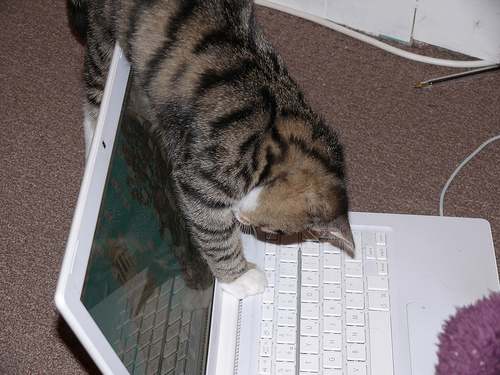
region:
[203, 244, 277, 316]
white paw of a cat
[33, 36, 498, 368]
white plastic laptop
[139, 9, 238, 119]
black stripes on a cat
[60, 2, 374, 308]
cat standing on laptop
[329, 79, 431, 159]
brown carpet on floor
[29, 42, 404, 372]
laptop on brown carpet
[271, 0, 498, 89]
white wire on carpet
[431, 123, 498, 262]
white cord attached to laptop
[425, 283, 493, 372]
purple fuzzy cloth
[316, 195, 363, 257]
ear of a cat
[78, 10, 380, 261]
This is a cat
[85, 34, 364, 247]
The cat is draped over a laptop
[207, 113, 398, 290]
The cat is looking at the computer screen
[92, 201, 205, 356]
There are many icons on the computer screen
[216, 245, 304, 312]
The cat's paw is on the keyboard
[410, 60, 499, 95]
Pen laying on the floor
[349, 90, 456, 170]
The floor is covered by carpet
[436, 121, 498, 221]
Cord connected to the computer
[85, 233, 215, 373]
Something that resembles the Capitol Building on the desktop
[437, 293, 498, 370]
Purple object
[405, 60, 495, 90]
a Bic pen on the carpet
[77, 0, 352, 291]
a tabby cat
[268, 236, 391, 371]
white keyboard of a laptop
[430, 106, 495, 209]
a gray wire on the carpet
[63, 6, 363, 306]
a cat touching a laptop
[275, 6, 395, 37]
a white wire along the wall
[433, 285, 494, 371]
fluffy purple fabric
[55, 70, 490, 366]
a white laptop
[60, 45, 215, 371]
opened lid of a laptop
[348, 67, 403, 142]
a brown carpet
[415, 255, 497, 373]
purple fuzzy toy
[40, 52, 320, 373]
a laptop computer screen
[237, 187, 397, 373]
white keyboard on a computer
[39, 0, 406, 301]
cat playing on laptop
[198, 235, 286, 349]
white cat paw on the computer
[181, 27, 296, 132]
gray and black stripes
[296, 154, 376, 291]
pink and brown cat ear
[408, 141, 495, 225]
white wire on the carpet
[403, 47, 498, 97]
uncapped pen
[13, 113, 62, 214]
clean brown carpet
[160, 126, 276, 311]
This is a leg of a cat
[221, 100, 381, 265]
This is a head of a cat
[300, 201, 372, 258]
This is an ear of a cat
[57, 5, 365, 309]
This is a grey cat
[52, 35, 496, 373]
This is a laptop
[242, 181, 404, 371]
This is a laptop keypad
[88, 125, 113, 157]
This is a laptop cam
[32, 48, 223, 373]
This is a laptop screen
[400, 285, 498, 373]
This is a laptop mouse area